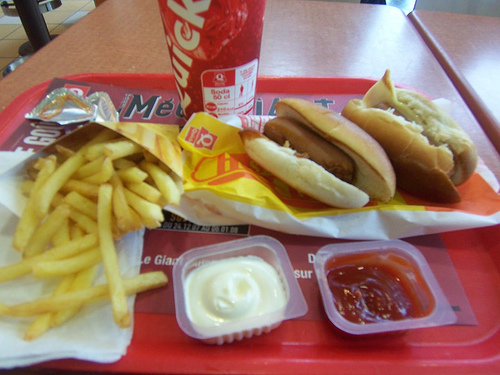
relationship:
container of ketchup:
[309, 235, 461, 340] [326, 258, 425, 331]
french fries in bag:
[1, 107, 186, 346] [1, 116, 181, 219]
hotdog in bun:
[256, 114, 360, 187] [242, 95, 398, 211]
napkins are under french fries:
[1, 146, 147, 371] [1, 107, 186, 346]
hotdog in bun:
[368, 97, 463, 181] [341, 67, 480, 206]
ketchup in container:
[326, 258, 425, 331] [309, 235, 461, 340]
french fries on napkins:
[1, 107, 186, 346] [1, 146, 147, 371]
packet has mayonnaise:
[167, 231, 313, 350] [182, 254, 291, 329]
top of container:
[20, 84, 123, 132] [309, 235, 461, 340]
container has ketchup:
[309, 235, 461, 340] [326, 258, 425, 331]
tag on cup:
[196, 55, 261, 129] [154, 1, 268, 120]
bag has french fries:
[1, 116, 181, 219] [1, 107, 186, 346]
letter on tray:
[119, 87, 162, 124] [2, 69, 498, 374]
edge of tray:
[4, 61, 101, 102] [2, 69, 498, 374]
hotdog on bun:
[256, 114, 360, 187] [242, 95, 398, 211]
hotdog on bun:
[368, 97, 463, 181] [341, 67, 480, 206]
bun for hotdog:
[242, 95, 398, 211] [256, 114, 360, 187]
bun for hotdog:
[341, 67, 480, 206] [368, 97, 463, 181]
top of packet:
[83, 88, 123, 125] [167, 231, 313, 350]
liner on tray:
[2, 74, 481, 335] [2, 69, 498, 374]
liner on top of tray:
[2, 74, 481, 335] [2, 69, 498, 374]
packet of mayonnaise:
[167, 231, 313, 350] [182, 254, 291, 329]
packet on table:
[167, 231, 313, 350] [0, 1, 499, 199]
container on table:
[309, 235, 461, 340] [0, 1, 499, 199]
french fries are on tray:
[1, 107, 186, 346] [2, 69, 498, 374]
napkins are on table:
[1, 146, 147, 371] [0, 1, 499, 199]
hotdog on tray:
[256, 114, 360, 187] [2, 69, 498, 374]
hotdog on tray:
[368, 97, 463, 181] [2, 69, 498, 374]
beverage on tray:
[154, 1, 268, 120] [2, 69, 498, 374]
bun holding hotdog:
[242, 95, 398, 211] [256, 114, 360, 187]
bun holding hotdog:
[341, 67, 480, 206] [368, 97, 463, 181]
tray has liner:
[2, 69, 498, 374] [2, 74, 481, 335]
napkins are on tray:
[1, 146, 147, 371] [2, 69, 498, 374]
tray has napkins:
[2, 69, 498, 374] [1, 146, 147, 371]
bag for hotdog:
[162, 109, 499, 241] [256, 114, 360, 187]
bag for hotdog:
[162, 109, 499, 241] [368, 97, 463, 181]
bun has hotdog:
[242, 95, 398, 211] [260, 115, 358, 187]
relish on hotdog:
[390, 97, 428, 124] [371, 100, 457, 180]